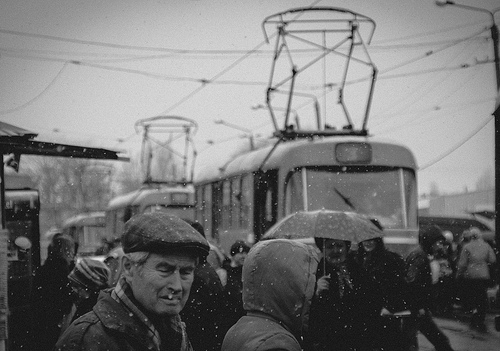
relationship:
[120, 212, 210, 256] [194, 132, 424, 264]
hat on bus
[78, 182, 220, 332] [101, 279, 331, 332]
gentleman wearing scarf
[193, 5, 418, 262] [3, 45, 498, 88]
tram connecting wires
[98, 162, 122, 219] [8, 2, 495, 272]
tree in background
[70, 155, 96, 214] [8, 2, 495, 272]
tree in background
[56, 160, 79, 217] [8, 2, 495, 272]
tree in background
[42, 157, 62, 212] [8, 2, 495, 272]
tree in background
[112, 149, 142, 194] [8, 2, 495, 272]
tree in background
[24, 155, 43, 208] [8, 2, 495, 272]
tree in background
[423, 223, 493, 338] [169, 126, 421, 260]
people to right of train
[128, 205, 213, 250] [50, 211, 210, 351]
cap on gentleman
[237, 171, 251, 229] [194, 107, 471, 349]
window on bus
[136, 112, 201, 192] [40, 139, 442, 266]
electric lines over train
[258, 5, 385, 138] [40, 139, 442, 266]
electric lines over train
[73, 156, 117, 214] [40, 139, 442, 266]
electric lines over train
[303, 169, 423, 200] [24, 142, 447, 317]
glass windshield over train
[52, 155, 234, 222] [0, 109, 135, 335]
snow over station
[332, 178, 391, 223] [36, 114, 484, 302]
wiper over train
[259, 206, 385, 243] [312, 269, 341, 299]
open umbrella in hand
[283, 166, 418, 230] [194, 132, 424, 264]
glass windshield on bus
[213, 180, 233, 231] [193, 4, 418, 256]
large window on tram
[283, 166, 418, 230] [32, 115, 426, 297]
glass windshield on bus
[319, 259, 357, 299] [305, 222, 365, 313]
scarf on woman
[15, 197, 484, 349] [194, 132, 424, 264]
people wait bus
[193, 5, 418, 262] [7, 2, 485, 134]
tram on line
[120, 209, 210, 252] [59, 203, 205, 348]
hat on man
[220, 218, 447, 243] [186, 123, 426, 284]
open umbrella near train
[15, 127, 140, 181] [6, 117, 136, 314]
awning in station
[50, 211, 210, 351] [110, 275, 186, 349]
gentleman has scarf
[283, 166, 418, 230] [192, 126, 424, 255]
glass windshield on train